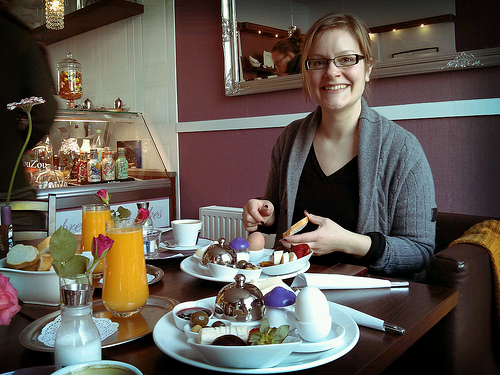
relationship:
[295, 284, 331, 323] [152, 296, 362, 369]
egg on platter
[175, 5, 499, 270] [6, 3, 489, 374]
wall side of building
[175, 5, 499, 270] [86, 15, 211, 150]
wall side of building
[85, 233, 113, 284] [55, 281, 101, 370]
flower in milk jar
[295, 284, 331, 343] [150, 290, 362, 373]
egg on platter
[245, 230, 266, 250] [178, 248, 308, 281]
egg on platter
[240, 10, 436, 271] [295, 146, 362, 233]
woman wearing shirt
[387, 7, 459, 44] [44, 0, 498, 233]
mirror on wall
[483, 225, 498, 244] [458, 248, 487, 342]
material on armchair